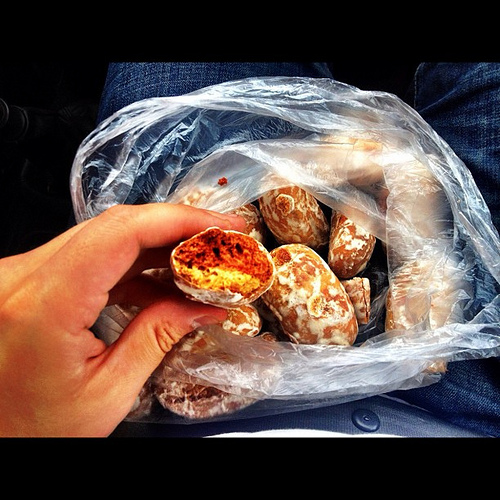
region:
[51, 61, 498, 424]
a bag of food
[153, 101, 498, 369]
a bag of donuts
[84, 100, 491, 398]
donuts in a bag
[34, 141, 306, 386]
a hand holding a food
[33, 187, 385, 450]
a hand holding a pastry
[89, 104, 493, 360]
a clear bag with food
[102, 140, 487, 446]
food in a clear bag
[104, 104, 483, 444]
pastries in a clear bag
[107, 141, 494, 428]
clear bag with pastries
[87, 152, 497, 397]
a bag on someones legs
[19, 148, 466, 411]
somebody is eating bite size snacks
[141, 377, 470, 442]
the person is wearing a seatbelt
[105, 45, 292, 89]
the person is wearing blue jeans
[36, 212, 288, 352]
the person is holding a piece of food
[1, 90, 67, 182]
the shift stick for the car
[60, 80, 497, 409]
the bite size snacks are in a plastic bag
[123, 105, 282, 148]
the plastic sack is clear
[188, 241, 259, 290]
the snacks appear to be stuffed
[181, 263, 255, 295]
one of the stuffed ingredients is yellow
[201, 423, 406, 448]
a little bit of the persons shirt can be seen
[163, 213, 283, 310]
This is some pastry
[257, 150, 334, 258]
This is some pastry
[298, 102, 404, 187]
This is some pastry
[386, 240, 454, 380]
This is some pastry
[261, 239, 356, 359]
This is some pastry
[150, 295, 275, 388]
This is some pastry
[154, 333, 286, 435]
This is some pastry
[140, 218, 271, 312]
Small food in hand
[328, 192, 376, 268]
Small brown and white food in bag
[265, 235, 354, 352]
Small brown and white food in bag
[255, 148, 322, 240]
Small brown and white food in bag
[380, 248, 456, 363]
Small brown and white food in bag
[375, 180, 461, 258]
Small brown and white food in bag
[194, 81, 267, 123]
Small part of a clear bag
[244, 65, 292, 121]
Small part of a clear bag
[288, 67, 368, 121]
Small part of a clear bag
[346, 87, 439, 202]
Small part of a clear bag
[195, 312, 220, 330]
The person's thumb nail.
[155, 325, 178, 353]
The knuckle area of the person's thumb.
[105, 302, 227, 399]
The thumb of the person holding the pastry.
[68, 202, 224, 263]
The index finger of the person.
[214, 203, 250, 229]
The tip of the person's middle finger.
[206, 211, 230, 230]
The tip of the person's index finger.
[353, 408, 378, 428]
The button on the seat belt.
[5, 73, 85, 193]
The gear shift of the car.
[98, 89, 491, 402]
The plastic bag the pastries are in.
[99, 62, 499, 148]
The jeans the person is wearing.